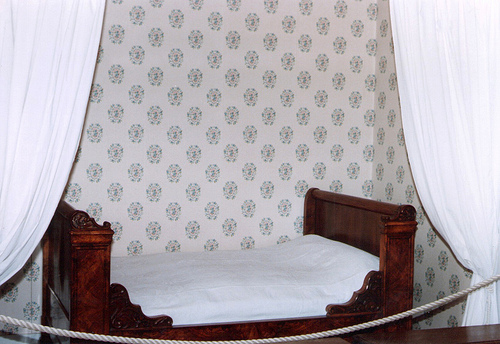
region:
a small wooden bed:
[37, 187, 421, 339]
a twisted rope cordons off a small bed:
[2, 272, 499, 342]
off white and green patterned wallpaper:
[0, 2, 492, 339]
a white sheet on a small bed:
[89, 228, 384, 327]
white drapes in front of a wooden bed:
[0, 3, 497, 328]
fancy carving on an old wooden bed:
[33, 182, 420, 337]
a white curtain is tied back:
[2, 2, 108, 325]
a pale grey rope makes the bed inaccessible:
[3, 269, 498, 341]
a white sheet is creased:
[105, 232, 380, 324]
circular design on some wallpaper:
[125, 122, 146, 144]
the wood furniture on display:
[37, 187, 415, 342]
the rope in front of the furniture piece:
[0, 273, 499, 343]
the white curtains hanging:
[0, 0, 498, 325]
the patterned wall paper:
[0, 0, 472, 336]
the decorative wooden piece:
[109, 282, 172, 324]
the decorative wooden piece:
[324, 270, 381, 313]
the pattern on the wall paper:
[241, 87, 258, 106]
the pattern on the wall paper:
[129, 5, 145, 25]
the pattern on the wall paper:
[125, 202, 142, 220]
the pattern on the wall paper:
[424, 266, 434, 286]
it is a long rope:
[9, 308, 456, 342]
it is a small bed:
[57, 207, 417, 334]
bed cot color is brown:
[53, 236, 103, 319]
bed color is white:
[131, 247, 316, 305]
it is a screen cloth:
[2, 102, 70, 189]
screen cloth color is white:
[12, 3, 477, 165]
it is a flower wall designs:
[103, 98, 339, 169]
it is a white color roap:
[13, 325, 138, 341]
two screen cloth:
[11, 15, 487, 237]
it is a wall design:
[203, 121, 222, 148]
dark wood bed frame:
[43, 185, 423, 342]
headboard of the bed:
[303, 188, 412, 320]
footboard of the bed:
[35, 201, 110, 341]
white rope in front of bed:
[0, 268, 499, 342]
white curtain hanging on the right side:
[392, 2, 495, 342]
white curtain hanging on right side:
[2, 4, 106, 334]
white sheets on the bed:
[107, 224, 372, 322]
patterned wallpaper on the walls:
[3, 5, 490, 335]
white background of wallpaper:
[30, 3, 462, 325]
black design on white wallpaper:
[17, 15, 461, 341]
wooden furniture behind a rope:
[57, 188, 405, 335]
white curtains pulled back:
[0, 0, 499, 277]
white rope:
[0, 276, 499, 342]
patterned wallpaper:
[110, 10, 366, 185]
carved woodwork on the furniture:
[108, 280, 175, 330]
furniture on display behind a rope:
[44, 193, 421, 335]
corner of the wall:
[354, 0, 384, 197]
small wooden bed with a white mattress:
[39, 180, 415, 332]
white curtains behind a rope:
[0, 2, 499, 273]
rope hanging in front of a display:
[3, 263, 490, 335]